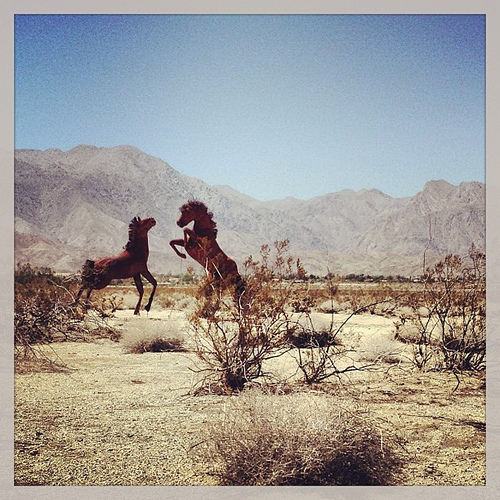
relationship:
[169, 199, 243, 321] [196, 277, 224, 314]
horse standing on hind legs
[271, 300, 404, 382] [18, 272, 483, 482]
sticks jutting out of ground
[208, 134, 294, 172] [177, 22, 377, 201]
clouds in sky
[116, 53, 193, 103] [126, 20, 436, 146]
clouds in sky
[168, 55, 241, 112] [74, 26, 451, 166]
clouds in blue sky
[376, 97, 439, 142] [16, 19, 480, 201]
clouds in sky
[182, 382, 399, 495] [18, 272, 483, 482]
bush on ground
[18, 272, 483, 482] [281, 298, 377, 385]
ground with twigs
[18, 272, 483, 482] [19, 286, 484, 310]
ground with grass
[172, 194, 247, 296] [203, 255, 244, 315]
horse on legs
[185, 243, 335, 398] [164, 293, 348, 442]
bush on land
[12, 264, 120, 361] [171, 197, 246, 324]
bush near horse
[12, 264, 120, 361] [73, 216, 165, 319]
bush near horse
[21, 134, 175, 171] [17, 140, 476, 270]
peak on mountain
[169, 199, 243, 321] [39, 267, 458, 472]
horse in dirt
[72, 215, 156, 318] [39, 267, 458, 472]
horse in dirt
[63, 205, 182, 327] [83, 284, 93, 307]
horse standing on leg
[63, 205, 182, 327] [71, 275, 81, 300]
horse standing on leg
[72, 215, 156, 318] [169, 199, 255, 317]
horse playing with horse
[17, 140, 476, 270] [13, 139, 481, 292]
mountain standing in background